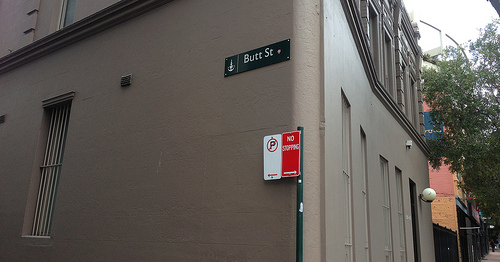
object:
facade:
[0, 0, 304, 262]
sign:
[260, 131, 301, 183]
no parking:
[281, 135, 301, 151]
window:
[22, 90, 71, 239]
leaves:
[417, 14, 499, 219]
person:
[487, 227, 497, 252]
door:
[407, 178, 422, 259]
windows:
[364, 2, 378, 62]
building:
[0, 1, 436, 262]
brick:
[429, 163, 457, 231]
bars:
[29, 162, 64, 167]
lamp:
[417, 187, 436, 203]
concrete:
[302, 1, 437, 260]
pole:
[294, 123, 304, 261]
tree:
[415, 16, 498, 260]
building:
[424, 46, 489, 262]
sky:
[404, 0, 494, 71]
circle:
[420, 188, 437, 200]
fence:
[433, 222, 458, 262]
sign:
[223, 39, 290, 80]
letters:
[241, 54, 250, 64]